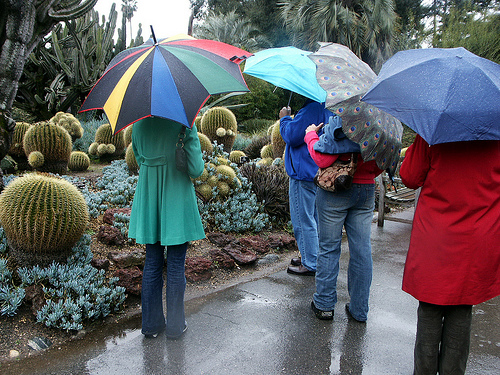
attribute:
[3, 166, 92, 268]
cactus — big, round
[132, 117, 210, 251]
coat — long, green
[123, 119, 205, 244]
jacket — green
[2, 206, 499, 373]
sidewalk — wet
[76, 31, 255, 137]
umbrella — bright, colored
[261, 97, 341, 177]
jacket — blue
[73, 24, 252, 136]
umbrella — colorful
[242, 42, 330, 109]
umbrella — light blue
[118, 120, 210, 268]
coat — green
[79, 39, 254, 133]
umbrella — multicolored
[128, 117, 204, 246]
coat — green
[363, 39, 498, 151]
umbrella — blue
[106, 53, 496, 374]
people — standing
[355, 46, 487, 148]
umbrella — blue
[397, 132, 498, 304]
coat — red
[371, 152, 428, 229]
bench — wooden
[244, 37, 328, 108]
umbrella — green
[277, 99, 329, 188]
coat — blue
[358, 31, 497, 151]
umbrella — blue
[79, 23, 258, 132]
umbrella — multi-colored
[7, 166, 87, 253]
needles — sharp